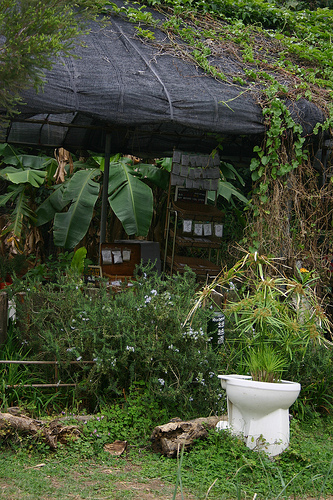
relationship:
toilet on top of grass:
[215, 365, 305, 461] [0, 408, 327, 499]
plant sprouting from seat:
[244, 342, 288, 381] [215, 365, 305, 461]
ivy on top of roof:
[109, 0, 316, 126] [20, 11, 325, 137]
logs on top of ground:
[145, 408, 226, 459] [0, 408, 327, 499]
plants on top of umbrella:
[0, 1, 332, 95] [0, 2, 329, 280]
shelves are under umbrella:
[164, 188, 230, 283] [0, 2, 329, 280]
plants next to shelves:
[47, 151, 152, 283] [164, 188, 230, 283]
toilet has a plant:
[215, 365, 305, 461] [228, 332, 297, 377]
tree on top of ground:
[145, 408, 226, 459] [0, 408, 327, 499]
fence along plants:
[3, 359, 138, 385] [16, 295, 219, 411]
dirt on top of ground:
[32, 460, 182, 499] [0, 408, 327, 499]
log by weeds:
[2, 408, 87, 455] [65, 355, 226, 434]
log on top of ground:
[145, 408, 226, 459] [0, 408, 327, 499]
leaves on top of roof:
[109, 0, 316, 126] [20, 11, 325, 137]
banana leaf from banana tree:
[107, 159, 154, 237] [47, 151, 152, 283]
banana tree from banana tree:
[51, 164, 103, 250] [47, 151, 152, 283]